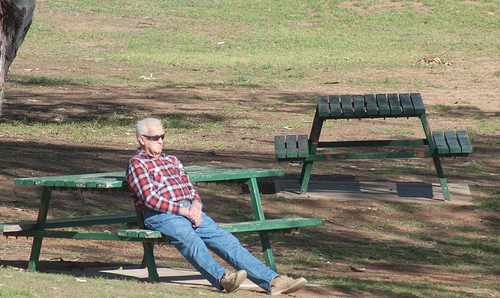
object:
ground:
[306, 210, 496, 282]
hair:
[136, 118, 163, 142]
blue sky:
[138, 207, 267, 288]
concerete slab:
[272, 172, 477, 207]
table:
[317, 91, 425, 114]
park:
[10, 1, 497, 296]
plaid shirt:
[124, 149, 200, 210]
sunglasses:
[139, 134, 164, 141]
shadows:
[276, 172, 361, 194]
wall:
[323, 113, 357, 165]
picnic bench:
[268, 92, 475, 194]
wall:
[289, 109, 334, 143]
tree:
[0, 0, 37, 88]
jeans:
[139, 201, 281, 292]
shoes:
[218, 270, 247, 294]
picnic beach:
[0, 165, 326, 281]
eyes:
[150, 137, 159, 140]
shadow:
[0, 89, 498, 295]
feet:
[220, 270, 249, 293]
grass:
[402, 221, 425, 227]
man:
[127, 117, 309, 295]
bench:
[2, 165, 324, 279]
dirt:
[359, 207, 430, 236]